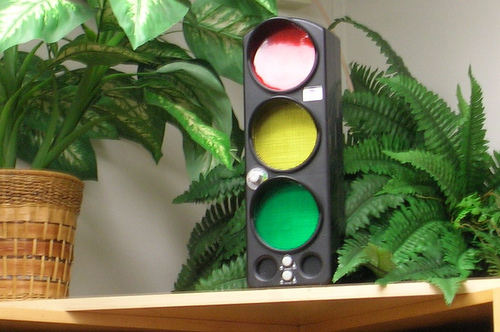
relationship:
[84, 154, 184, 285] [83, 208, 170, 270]
shadow cast wall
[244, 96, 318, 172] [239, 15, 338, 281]
sign representative of traffic light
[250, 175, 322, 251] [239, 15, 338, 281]
sign representative of traffic light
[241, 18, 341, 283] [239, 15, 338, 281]
replica of traffic light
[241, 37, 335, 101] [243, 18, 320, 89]
reflection on shade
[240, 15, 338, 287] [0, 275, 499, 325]
light on table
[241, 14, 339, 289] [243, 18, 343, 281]
table with light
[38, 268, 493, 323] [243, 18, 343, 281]
table with light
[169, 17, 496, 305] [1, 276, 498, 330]
fern on shelf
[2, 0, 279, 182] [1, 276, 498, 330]
leaves on shelf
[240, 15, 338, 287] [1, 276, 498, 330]
light on shelf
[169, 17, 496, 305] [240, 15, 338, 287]
fern behind light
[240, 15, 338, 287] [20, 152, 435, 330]
light on table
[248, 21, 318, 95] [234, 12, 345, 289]
red part of traffic light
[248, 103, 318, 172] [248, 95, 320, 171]
yellow part of light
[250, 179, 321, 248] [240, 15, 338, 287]
part of light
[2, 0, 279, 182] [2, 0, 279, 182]
leaves with leaves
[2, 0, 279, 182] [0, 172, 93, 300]
leaves in pot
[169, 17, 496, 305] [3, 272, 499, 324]
fern on shelf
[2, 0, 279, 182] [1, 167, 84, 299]
leaves in basket